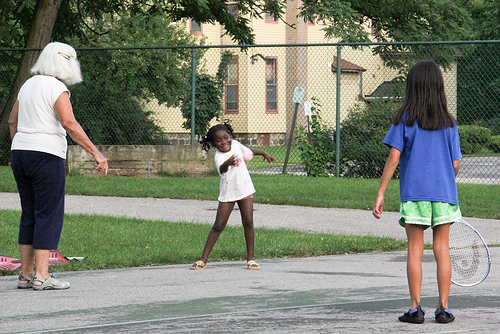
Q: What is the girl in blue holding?
A: Tennis racket.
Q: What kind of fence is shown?
A: Chain link.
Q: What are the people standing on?
A: Road.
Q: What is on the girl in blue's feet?
A: Sandals.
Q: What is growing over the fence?
A: Trees.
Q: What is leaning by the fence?
A: A sign.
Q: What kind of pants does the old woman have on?
A: Capris.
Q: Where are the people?
A: Tennis court.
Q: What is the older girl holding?
A: Tennis racket.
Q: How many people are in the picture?
A: Three.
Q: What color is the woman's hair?
A: Gray.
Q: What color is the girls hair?
A: Black.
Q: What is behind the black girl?
A: Fence.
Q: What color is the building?
A: Beige.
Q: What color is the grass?
A: Green.